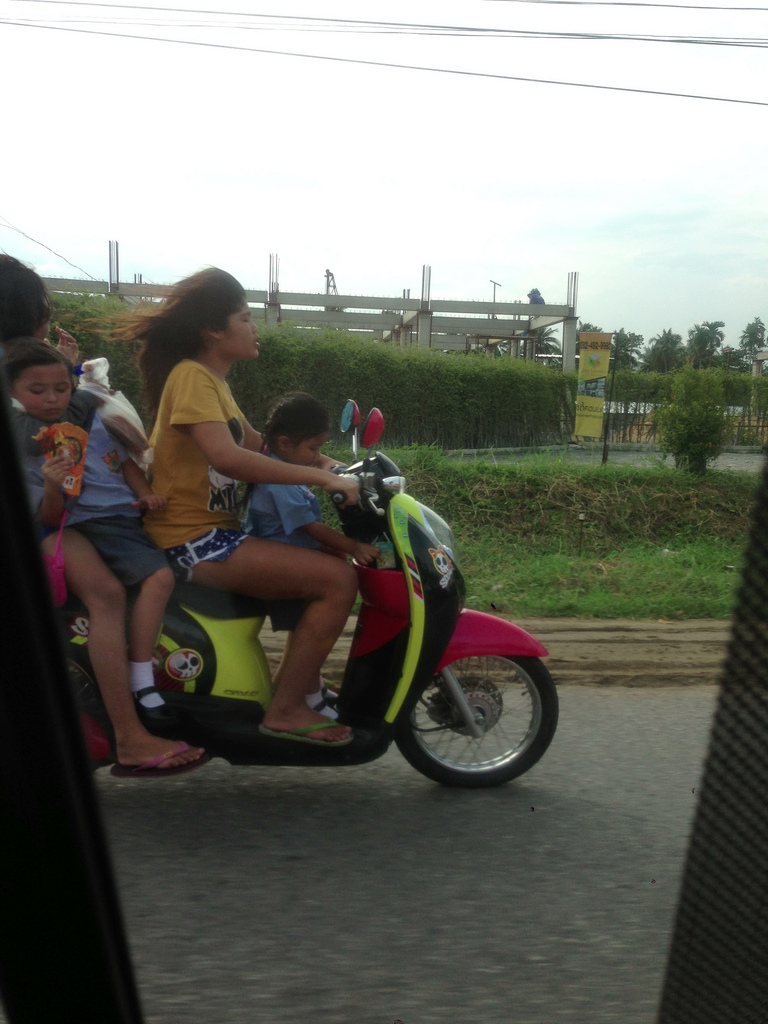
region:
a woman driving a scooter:
[133, 282, 363, 747]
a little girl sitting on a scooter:
[248, 393, 378, 733]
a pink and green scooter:
[38, 404, 561, 792]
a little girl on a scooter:
[2, 339, 187, 717]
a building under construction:
[1, 238, 582, 361]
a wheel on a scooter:
[388, 650, 561, 792]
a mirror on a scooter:
[337, 394, 355, 435]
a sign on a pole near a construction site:
[574, 331, 608, 442]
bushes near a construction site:
[0, 289, 576, 445]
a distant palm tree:
[679, 317, 721, 369]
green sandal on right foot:
[257, 703, 357, 754]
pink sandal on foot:
[104, 737, 213, 779]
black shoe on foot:
[132, 683, 186, 729]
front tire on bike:
[393, 619, 564, 798]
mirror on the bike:
[333, 394, 360, 455]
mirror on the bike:
[356, 407, 395, 461]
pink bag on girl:
[43, 506, 82, 609]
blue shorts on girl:
[158, 510, 245, 583]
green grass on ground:
[520, 545, 748, 621]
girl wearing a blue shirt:
[238, 391, 381, 720]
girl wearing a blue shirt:
[0, 340, 173, 727]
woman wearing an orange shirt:
[88, 270, 354, 746]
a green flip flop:
[260, 717, 354, 742]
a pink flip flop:
[110, 741, 208, 775]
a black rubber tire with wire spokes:
[396, 655, 561, 785]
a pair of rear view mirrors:
[335, 397, 384, 445]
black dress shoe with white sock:
[129, 661, 179, 727]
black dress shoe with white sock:
[307, 689, 344, 720]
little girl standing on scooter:
[237, 391, 369, 738]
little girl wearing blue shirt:
[238, 463, 337, 569]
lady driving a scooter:
[118, 258, 381, 760]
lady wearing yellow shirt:
[141, 366, 260, 532]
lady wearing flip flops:
[259, 700, 357, 759]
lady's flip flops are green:
[254, 701, 357, 753]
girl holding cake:
[26, 418, 65, 466]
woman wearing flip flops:
[104, 733, 217, 779]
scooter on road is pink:
[8, 379, 571, 805]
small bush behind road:
[645, 360, 731, 476]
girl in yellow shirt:
[141, 262, 569, 780]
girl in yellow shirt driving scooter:
[147, 259, 562, 784]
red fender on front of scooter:
[394, 607, 567, 792]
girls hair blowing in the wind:
[97, 266, 268, 385]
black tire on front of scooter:
[386, 618, 565, 794]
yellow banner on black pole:
[561, 324, 618, 462]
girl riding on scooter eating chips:
[11, 345, 429, 799]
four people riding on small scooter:
[5, 254, 571, 793]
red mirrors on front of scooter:
[335, 396, 406, 494]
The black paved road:
[77, 664, 676, 1019]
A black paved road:
[88, 664, 715, 1020]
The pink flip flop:
[105, 722, 228, 799]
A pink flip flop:
[100, 727, 228, 799]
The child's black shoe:
[111, 638, 204, 743]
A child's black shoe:
[120, 651, 204, 729]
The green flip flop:
[244, 694, 372, 777]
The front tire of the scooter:
[374, 615, 596, 808]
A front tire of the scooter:
[380, 640, 576, 799]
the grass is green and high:
[588, 552, 661, 592]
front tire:
[415, 678, 547, 782]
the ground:
[366, 922, 493, 1014]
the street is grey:
[471, 916, 526, 975]